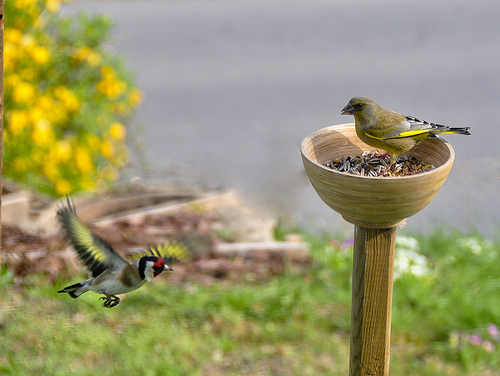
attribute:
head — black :
[132, 253, 178, 282]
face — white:
[132, 251, 176, 286]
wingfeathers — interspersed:
[52, 195, 128, 272]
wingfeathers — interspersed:
[129, 239, 196, 264]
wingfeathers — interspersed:
[375, 113, 435, 140]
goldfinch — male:
[337, 92, 440, 170]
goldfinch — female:
[45, 203, 184, 316]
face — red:
[147, 256, 174, 271]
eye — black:
[351, 101, 365, 108]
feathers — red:
[366, 105, 395, 139]